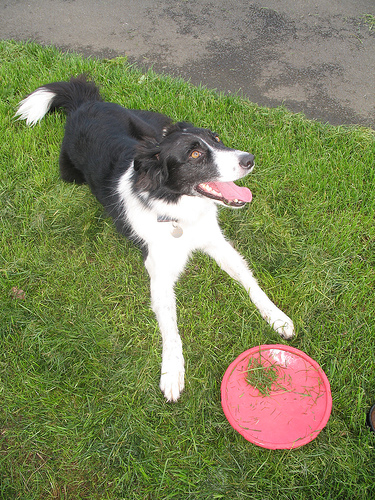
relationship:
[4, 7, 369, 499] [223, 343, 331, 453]
scene shows a frisbee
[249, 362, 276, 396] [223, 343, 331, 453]
grass on frisbee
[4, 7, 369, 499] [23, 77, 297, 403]
scene shows dog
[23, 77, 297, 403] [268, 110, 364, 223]
dog lying on yard grass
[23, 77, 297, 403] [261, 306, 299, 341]
dog has paw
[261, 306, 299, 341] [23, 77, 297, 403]
paw part of dog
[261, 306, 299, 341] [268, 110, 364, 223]
paw on top of yard grass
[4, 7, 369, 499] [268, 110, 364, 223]
scene shows dirt patch in yard grass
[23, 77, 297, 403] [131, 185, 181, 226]
dog has collar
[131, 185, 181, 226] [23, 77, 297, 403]
collar with tag on dog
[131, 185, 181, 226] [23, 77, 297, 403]
collar on lying dog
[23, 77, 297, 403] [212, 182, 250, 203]
dog has tongue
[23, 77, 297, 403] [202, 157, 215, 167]
dog has eye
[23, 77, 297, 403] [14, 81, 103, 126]
dog has tail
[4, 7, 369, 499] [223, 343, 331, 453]
scene shows frisbee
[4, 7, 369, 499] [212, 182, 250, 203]
scene shows dogs tongue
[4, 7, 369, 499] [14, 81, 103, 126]
scene has a dogs tail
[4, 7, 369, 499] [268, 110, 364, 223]
scene shows yard grass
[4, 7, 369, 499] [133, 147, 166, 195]
scene shows dogs ear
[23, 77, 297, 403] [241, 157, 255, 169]
dog has a nose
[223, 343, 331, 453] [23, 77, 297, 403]
frisbee next to dog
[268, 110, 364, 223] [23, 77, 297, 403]
yard grass next to dog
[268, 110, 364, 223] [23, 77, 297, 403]
yard grass all around dog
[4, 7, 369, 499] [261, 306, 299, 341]
scene shows dogs paw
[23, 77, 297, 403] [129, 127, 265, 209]
dog has head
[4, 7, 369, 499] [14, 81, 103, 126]
scene shows dogs tail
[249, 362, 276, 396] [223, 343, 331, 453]
grass on top of frisbee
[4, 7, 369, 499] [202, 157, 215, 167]
scene shows dogs eye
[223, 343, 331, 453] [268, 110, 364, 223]
frisbee lies on yard grass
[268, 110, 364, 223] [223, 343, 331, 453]
yard grass near frisbee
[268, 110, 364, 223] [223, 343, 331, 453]
yard grass all around frisbee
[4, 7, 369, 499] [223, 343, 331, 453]
scene shows edge of a frisbee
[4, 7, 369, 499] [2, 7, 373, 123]
scene shows street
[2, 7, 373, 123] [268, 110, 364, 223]
street next to yard grass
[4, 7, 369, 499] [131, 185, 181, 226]
scene shows round tag on dog collar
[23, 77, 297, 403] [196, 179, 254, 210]
dog has mouth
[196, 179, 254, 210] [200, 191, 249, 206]
mouth has teeth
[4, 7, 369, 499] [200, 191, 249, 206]
scene shows row of canine teeth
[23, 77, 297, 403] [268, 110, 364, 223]
dog lying on area of yard grass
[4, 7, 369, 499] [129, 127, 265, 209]
scene shows dogs head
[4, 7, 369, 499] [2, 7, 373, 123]
scene shows blacktop of street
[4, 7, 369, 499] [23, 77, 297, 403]
scene has black and white dog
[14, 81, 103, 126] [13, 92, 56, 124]
tail has tip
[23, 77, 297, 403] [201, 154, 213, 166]
dog has right eye